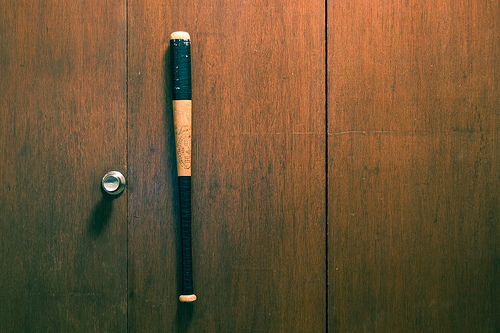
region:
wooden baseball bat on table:
[169, 30, 199, 305]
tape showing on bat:
[172, 36, 192, 100]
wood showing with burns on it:
[173, 100, 193, 174]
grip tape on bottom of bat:
[178, 175, 193, 295]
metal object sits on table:
[101, 169, 125, 195]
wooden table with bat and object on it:
[0, 0, 499, 331]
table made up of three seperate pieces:
[1, 0, 498, 331]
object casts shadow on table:
[86, 170, 126, 243]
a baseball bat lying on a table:
[5, 1, 481, 323]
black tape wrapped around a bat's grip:
[170, 177, 224, 295]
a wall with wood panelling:
[22, 15, 487, 325]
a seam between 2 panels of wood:
[296, 10, 359, 301]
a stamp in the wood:
[160, 113, 202, 181]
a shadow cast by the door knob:
[72, 184, 132, 241]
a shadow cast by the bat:
[157, 300, 199, 331]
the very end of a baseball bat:
[175, 293, 205, 303]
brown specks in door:
[369, 8, 386, 41]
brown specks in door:
[339, 72, 376, 112]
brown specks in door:
[394, 68, 424, 100]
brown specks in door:
[271, 27, 323, 79]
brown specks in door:
[214, 19, 259, 81]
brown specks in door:
[91, 73, 121, 136]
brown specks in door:
[203, 130, 248, 180]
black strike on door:
[267, 75, 299, 127]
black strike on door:
[353, 94, 379, 136]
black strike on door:
[337, 258, 402, 305]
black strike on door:
[66, 118, 118, 176]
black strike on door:
[39, 214, 110, 281]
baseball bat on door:
[144, 24, 236, 313]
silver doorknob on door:
[78, 160, 145, 202]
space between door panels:
[311, 9, 346, 326]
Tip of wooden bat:
[161, 26, 196, 40]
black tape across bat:
[161, 40, 198, 100]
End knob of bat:
[171, 294, 205, 306]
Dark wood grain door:
[8, 14, 91, 306]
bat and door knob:
[74, 11, 240, 315]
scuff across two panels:
[270, 113, 397, 152]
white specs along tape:
[169, 46, 184, 98]